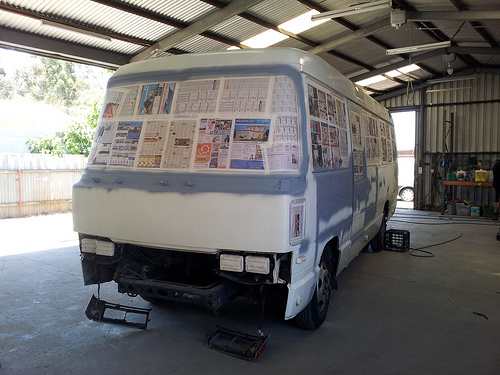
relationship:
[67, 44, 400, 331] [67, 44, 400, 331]
old van old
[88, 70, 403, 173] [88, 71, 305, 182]
newspaper taped to windshield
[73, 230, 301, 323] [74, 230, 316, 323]
front bumper off van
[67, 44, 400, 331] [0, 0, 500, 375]
old in garage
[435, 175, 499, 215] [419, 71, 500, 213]
table against corrugated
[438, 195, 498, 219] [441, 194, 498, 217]
boxes near wall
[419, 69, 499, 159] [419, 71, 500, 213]
corrugated metal corrugated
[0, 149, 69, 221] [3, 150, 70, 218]
fence behind warehouse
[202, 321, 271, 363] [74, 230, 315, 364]
left side bumper off van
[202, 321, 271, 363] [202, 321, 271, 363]
left side headlight left side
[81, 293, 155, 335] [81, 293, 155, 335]
right side headlight right side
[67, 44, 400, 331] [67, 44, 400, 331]
old being old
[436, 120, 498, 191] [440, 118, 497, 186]
equiptment for painting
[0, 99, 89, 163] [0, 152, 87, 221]
trees over fence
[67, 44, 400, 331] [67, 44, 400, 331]
old vw old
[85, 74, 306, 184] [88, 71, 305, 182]
newspapers covering windshield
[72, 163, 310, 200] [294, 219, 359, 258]
blue paint spots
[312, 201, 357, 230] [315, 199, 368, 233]
white paint spots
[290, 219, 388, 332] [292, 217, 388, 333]
tires on van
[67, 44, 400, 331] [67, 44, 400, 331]
old with old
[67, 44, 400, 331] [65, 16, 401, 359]
old in garage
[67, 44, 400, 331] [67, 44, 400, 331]
old and grey old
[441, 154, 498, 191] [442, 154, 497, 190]
rack with tools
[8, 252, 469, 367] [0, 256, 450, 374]
concrete below van